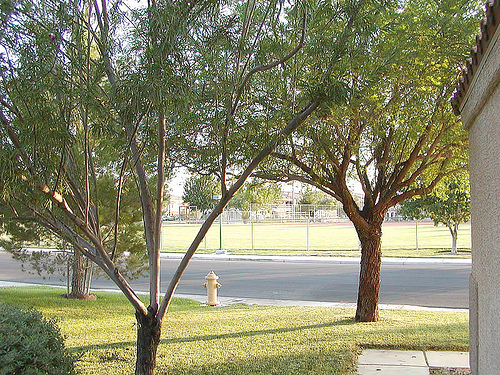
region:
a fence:
[227, 211, 331, 291]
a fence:
[224, 195, 312, 269]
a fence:
[240, 185, 355, 303]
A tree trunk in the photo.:
[135, 317, 164, 374]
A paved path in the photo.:
[372, 350, 422, 369]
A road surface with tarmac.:
[276, 266, 336, 290]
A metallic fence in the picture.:
[283, 217, 318, 247]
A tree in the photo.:
[313, 76, 395, 324]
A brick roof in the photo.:
[444, 44, 481, 91]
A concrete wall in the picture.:
[455, 168, 497, 367]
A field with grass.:
[220, 325, 277, 357]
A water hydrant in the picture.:
[201, 269, 229, 311]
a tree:
[361, 220, 437, 341]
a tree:
[326, 182, 375, 337]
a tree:
[328, 97, 396, 304]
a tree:
[358, 129, 394, 309]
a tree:
[324, 62, 489, 362]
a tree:
[304, 50, 420, 353]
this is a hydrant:
[205, 273, 217, 293]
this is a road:
[251, 252, 311, 292]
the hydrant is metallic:
[201, 268, 216, 305]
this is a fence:
[235, 212, 300, 237]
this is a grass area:
[220, 310, 297, 365]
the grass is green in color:
[215, 320, 275, 362]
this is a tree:
[340, 71, 411, 241]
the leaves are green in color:
[335, 30, 400, 90]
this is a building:
[460, 60, 495, 315]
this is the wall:
[470, 163, 496, 216]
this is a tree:
[347, 198, 390, 322]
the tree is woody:
[351, 215, 386, 325]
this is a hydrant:
[203, 268, 224, 305]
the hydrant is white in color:
[201, 267, 221, 305]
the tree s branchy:
[69, 144, 238, 340]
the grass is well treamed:
[255, 310, 310, 373]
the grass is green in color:
[250, 316, 307, 366]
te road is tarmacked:
[290, 264, 323, 292]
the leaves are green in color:
[386, 17, 441, 85]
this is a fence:
[268, 205, 310, 244]